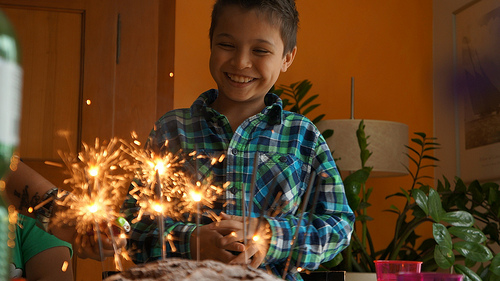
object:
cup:
[373, 259, 461, 281]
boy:
[118, 1, 357, 280]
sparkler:
[192, 171, 207, 267]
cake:
[107, 259, 286, 279]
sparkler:
[148, 159, 169, 262]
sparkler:
[243, 150, 270, 268]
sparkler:
[80, 190, 108, 279]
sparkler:
[281, 167, 317, 280]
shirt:
[119, 89, 357, 280]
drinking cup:
[372, 258, 425, 280]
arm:
[1, 152, 73, 218]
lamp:
[303, 72, 410, 269]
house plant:
[274, 79, 499, 281]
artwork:
[449, 2, 499, 178]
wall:
[174, 2, 499, 261]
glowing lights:
[135, 141, 183, 193]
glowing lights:
[172, 171, 219, 222]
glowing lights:
[60, 129, 126, 195]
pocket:
[245, 150, 311, 215]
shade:
[314, 117, 410, 177]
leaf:
[407, 185, 475, 226]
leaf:
[429, 221, 461, 266]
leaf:
[276, 77, 335, 143]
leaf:
[355, 117, 374, 169]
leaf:
[343, 164, 377, 211]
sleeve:
[16, 212, 76, 257]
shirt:
[0, 202, 74, 280]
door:
[2, 0, 125, 279]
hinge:
[112, 11, 125, 67]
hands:
[189, 220, 250, 264]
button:
[232, 148, 238, 154]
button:
[279, 156, 287, 162]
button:
[230, 186, 238, 194]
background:
[0, 0, 500, 245]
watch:
[36, 186, 61, 234]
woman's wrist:
[29, 188, 61, 225]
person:
[0, 16, 133, 259]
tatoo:
[9, 185, 51, 218]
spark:
[86, 99, 92, 105]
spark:
[134, 140, 142, 146]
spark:
[217, 153, 226, 162]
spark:
[26, 208, 34, 214]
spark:
[188, 150, 198, 158]